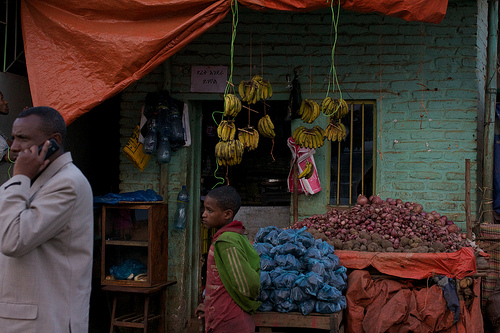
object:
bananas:
[222, 95, 229, 115]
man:
[2, 105, 101, 332]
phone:
[31, 138, 61, 161]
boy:
[198, 186, 266, 333]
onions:
[356, 193, 368, 204]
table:
[333, 246, 478, 332]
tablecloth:
[333, 247, 475, 281]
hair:
[204, 182, 242, 214]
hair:
[16, 104, 69, 144]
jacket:
[1, 153, 96, 332]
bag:
[105, 258, 148, 280]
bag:
[257, 226, 279, 243]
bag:
[310, 238, 332, 260]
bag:
[303, 274, 334, 294]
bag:
[257, 252, 281, 273]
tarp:
[19, 2, 233, 128]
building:
[112, 2, 488, 332]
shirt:
[202, 222, 254, 327]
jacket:
[202, 225, 266, 313]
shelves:
[96, 195, 166, 290]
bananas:
[238, 80, 245, 98]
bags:
[272, 270, 300, 287]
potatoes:
[333, 238, 342, 249]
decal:
[206, 249, 225, 299]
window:
[326, 97, 376, 205]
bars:
[359, 103, 367, 204]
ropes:
[224, 1, 239, 93]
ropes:
[321, 1, 343, 117]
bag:
[96, 189, 163, 206]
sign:
[189, 64, 230, 93]